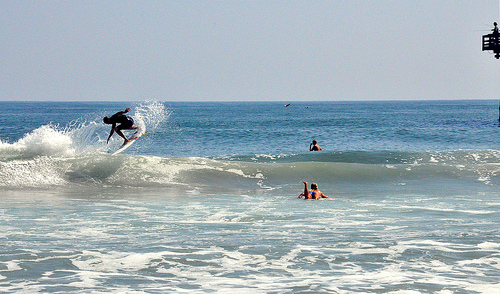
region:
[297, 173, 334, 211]
a person swimming in the water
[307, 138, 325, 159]
a person floating in the water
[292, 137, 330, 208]
people swimming in the ocean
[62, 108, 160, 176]
a surfer in motion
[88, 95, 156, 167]
a person surfboarding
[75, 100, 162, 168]
a surfboarder riding a wave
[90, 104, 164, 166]
a person surfing in the water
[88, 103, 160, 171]
a surfer riding a wave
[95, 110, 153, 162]
a surfer in a black outfit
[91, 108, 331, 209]
people in the ocean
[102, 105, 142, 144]
A man in a black wetsuit on a surfboard.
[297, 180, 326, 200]
A woman in a blue bikini lying on a surfboard.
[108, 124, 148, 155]
A surfboard under a man surfing.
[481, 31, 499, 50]
A black deck over the water.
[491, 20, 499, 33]
A person up on a deck fishing.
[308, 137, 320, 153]
A man in the water past the girl on a surfboard.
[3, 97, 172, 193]
White waves all around the surfer.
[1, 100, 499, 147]
Calmer bluer water.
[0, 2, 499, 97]
Blue grey sky over the water.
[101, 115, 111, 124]
Head of a man on a surfboard.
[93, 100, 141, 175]
man surfing on board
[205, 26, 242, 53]
white clouds in blue sky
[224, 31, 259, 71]
white clouds in blue sky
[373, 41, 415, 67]
white clouds in blue sky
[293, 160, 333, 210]
person swimming in ocean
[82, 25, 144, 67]
white clouds in blue sky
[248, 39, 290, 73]
white clouds in blue sky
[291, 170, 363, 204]
tan person in water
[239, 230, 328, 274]
white wave in water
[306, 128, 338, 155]
tan person in water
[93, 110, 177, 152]
person surfing in water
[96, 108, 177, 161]
person in black suit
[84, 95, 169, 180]
person on surf board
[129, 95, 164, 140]
white wave behind person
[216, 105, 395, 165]
blue water behind person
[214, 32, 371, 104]
clear sky behind water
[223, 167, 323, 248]
dirty water behind person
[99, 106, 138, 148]
a surfer flying high above the wave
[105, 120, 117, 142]
the arm of the surfer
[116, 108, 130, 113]
the arm of the surfer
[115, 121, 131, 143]
the leg of the surfer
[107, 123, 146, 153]
the white surfboard under the surfer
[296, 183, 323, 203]
the woman surfer in the water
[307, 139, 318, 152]
the person in the water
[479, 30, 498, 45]
the dark pier above the water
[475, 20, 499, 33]
the person fishing on the dock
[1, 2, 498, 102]
the light blue sky